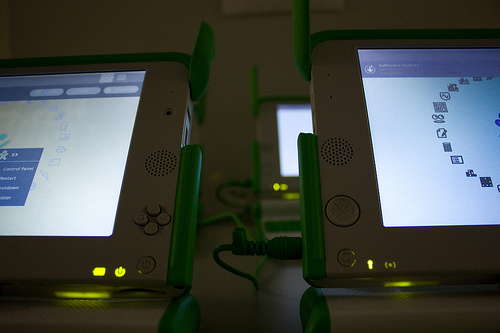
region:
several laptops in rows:
[1, 1, 498, 331]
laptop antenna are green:
[181, 0, 311, 124]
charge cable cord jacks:
[194, 173, 302, 290]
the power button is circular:
[136, 255, 159, 272]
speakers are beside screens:
[144, 135, 358, 178]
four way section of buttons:
[133, 201, 173, 235]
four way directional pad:
[321, 195, 363, 226]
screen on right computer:
[352, 39, 499, 226]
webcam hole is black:
[161, 106, 176, 122]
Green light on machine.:
[380, 257, 403, 274]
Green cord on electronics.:
[215, 223, 299, 290]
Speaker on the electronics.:
[314, 130, 359, 173]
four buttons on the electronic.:
[131, 196, 173, 237]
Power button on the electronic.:
[110, 260, 130, 279]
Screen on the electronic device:
[4, 70, 148, 240]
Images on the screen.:
[422, 77, 498, 201]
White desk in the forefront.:
[0, 220, 497, 329]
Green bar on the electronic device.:
[290, 128, 327, 280]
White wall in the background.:
[2, 1, 496, 229]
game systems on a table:
[12, 25, 497, 330]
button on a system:
[322, 188, 362, 232]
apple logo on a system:
[108, 261, 130, 286]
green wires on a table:
[206, 194, 261, 301]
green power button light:
[380, 250, 430, 292]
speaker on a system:
[141, 139, 178, 184]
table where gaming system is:
[209, 277, 294, 325]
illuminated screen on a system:
[371, 55, 472, 232]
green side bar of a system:
[288, 117, 324, 290]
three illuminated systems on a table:
[6, 10, 484, 323]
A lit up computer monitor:
[6, 25, 228, 297]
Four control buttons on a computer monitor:
[123, 193, 180, 242]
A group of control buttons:
[130, 198, 175, 247]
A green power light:
[109, 263, 131, 280]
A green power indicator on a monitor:
[108, 263, 130, 282]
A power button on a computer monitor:
[131, 251, 165, 276]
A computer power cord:
[206, 223, 303, 278]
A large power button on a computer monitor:
[322, 185, 363, 235]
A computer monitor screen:
[345, 44, 499, 237]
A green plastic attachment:
[288, 123, 333, 284]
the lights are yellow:
[90, 265, 122, 280]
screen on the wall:
[365, 82, 467, 219]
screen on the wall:
[275, 109, 309, 176]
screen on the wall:
[10, 98, 122, 237]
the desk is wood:
[201, 283, 261, 310]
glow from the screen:
[366, 275, 430, 287]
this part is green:
[168, 129, 197, 290]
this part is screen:
[292, 25, 309, 77]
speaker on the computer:
[318, 132, 358, 169]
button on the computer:
[136, 250, 156, 276]